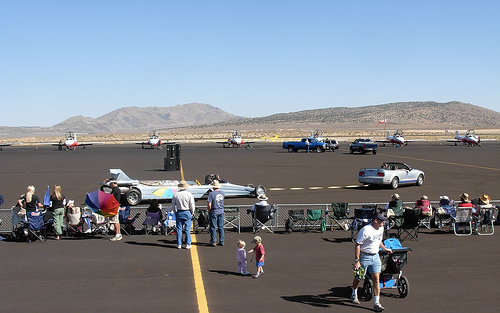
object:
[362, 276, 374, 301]
wheels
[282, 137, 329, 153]
pickup truck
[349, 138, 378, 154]
pickup truck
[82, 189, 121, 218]
umbrella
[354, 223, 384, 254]
shirt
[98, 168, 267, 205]
car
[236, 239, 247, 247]
hair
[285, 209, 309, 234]
lawn chair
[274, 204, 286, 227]
gate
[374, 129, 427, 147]
airplane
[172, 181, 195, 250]
man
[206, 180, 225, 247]
man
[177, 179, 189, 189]
white hat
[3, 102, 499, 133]
mountains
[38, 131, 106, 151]
airplane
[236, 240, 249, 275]
child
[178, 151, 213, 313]
yellow line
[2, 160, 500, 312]
road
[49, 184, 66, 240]
woman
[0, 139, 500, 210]
track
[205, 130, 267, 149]
airplane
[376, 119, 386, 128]
flag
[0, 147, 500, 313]
plane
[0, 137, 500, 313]
tarmac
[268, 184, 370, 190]
line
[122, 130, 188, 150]
airplane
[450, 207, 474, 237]
chair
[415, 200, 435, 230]
chair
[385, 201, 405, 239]
chair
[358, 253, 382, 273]
blue shorts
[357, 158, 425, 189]
car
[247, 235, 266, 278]
child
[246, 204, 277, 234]
lawn chair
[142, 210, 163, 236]
lawn chair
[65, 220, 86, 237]
lawn chair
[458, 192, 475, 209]
person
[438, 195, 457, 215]
person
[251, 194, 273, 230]
person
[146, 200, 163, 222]
person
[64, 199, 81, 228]
person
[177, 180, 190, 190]
hat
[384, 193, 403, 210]
person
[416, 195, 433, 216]
person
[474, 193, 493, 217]
person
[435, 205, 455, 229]
chair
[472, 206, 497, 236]
chair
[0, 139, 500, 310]
airport track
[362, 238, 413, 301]
baby stroller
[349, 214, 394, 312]
man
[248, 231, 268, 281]
kid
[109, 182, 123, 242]
man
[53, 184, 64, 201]
hair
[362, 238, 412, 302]
stroller